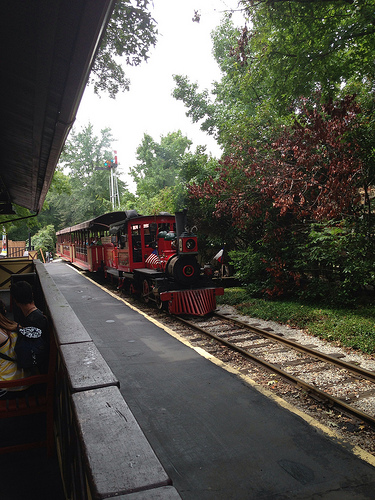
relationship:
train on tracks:
[54, 209, 226, 317] [166, 307, 367, 423]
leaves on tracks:
[267, 379, 367, 434] [166, 307, 367, 423]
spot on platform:
[106, 318, 114, 325] [41, 259, 367, 493]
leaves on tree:
[186, 92, 366, 231] [186, 87, 372, 295]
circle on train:
[182, 264, 196, 279] [54, 209, 226, 317]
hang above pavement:
[5, 1, 111, 227] [41, 259, 367, 493]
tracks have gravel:
[166, 307, 367, 423] [208, 322, 369, 411]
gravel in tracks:
[208, 322, 369, 411] [166, 307, 367, 423]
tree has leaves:
[186, 87, 372, 295] [186, 92, 366, 231]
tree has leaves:
[171, 6, 370, 177] [219, 5, 366, 111]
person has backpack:
[1, 313, 29, 395] [15, 326, 44, 370]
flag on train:
[144, 248, 158, 264] [54, 209, 226, 317]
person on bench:
[11, 282, 53, 375] [1, 327, 60, 467]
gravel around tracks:
[256, 373, 372, 441] [166, 307, 367, 423]